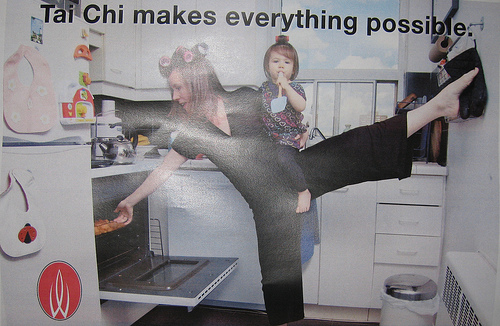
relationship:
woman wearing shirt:
[166, 62, 416, 299] [186, 114, 294, 188]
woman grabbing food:
[113, 42, 478, 326] [93, 216, 124, 236]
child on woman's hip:
[254, 30, 316, 143] [245, 120, 335, 171]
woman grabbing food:
[113, 42, 478, 326] [93, 200, 136, 243]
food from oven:
[93, 200, 136, 243] [74, 150, 239, 315]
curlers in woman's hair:
[152, 43, 214, 65] [166, 38, 242, 128]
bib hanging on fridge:
[8, 40, 65, 135] [1, 0, 105, 323]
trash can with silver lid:
[376, 267, 436, 324] [374, 267, 458, 308]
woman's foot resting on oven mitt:
[430, 60, 480, 130] [441, 33, 493, 123]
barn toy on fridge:
[57, 82, 99, 122] [1, 0, 105, 323]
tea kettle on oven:
[101, 130, 135, 162] [92, 169, 238, 307]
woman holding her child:
[113, 42, 478, 326] [225, 27, 323, 155]